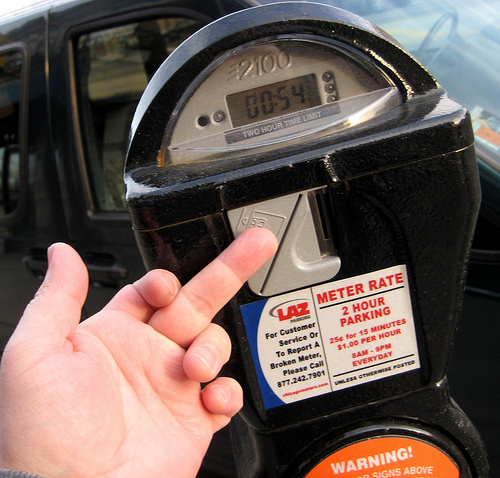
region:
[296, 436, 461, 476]
The orange sticker on the meter.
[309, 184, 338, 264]
The coin slot on the meter.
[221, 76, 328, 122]
The time display on the meter.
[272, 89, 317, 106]
The number 54 on the meter screen.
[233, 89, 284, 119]
The double zeroes on the meter screen.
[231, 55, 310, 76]
The number 2100 on the meter.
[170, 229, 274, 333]
The person's middle finger.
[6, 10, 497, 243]
The black vehicle behind the parking meter.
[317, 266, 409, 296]
The words Meter Rate on the sticker.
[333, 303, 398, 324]
The words 2 Hour Parking on the sticker.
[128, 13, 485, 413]
a black parking meter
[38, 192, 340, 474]
the person is shooting the meter a bird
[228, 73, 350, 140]
the meter has 54 minutes on it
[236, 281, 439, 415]
the tag is red white & blue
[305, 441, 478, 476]
the warning sticker is orange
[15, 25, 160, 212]
a vehicle is parked in the background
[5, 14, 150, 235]
the vehicle is dark in color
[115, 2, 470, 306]
the coin slot is grey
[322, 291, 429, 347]
the meter says 2 hour parking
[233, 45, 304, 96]
the number 2100 is on the top of the meter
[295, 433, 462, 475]
orange sticker on parking meter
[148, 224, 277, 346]
extended middle finger of hand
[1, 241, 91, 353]
thumb on hand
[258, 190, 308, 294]
middle finger pointing to coin slot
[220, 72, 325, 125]
LCD display on parking meter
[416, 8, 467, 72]
steering visible behind parking meter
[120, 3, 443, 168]
black dome shaped top of parking meter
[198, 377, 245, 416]
pinkie finger is bent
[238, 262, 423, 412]
white sticker on parking meter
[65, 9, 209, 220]
car window behind parking meter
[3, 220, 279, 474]
hand with extended middle finger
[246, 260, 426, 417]
tag with parking meter rates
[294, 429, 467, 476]
orange warning sign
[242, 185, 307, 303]
slot for parking payment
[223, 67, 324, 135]
screen displaying parking time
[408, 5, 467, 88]
steering wheel of background vehicle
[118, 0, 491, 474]
black parking meter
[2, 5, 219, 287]
black doors of background vehicle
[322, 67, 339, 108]
three LED lights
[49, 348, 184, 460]
palm of left hand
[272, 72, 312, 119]
The time remaining on the meter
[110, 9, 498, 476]
A parking meter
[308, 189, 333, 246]
The coin slot on the meter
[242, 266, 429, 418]
A sticker on the meter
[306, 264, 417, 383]
A sign explaining the rate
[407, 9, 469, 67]
The steering wheel of a car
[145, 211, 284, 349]
An extended middle finger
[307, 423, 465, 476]
An orange warning sticker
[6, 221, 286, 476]
A person's hand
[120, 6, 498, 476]
The parking meter is metal